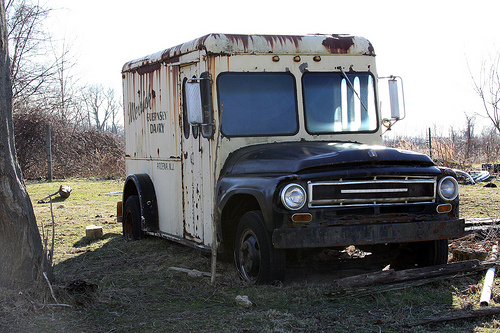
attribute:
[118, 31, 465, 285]
truck — junk, old, white, rusty, rusting, worn out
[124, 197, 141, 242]
wheel — rubber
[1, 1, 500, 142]
sky — bright, clear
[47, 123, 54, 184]
pole — metal